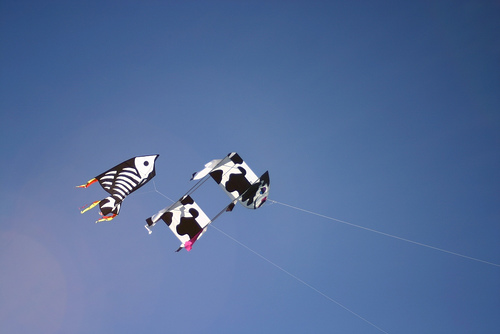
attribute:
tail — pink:
[176, 234, 202, 264]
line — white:
[276, 187, 442, 270]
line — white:
[105, 162, 134, 194]